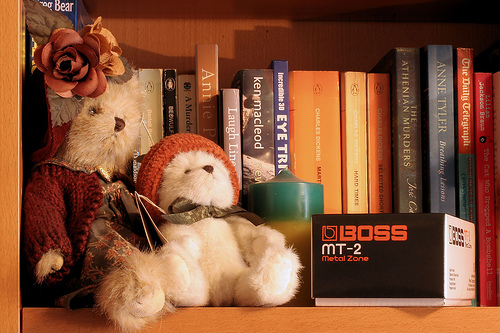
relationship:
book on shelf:
[426, 42, 461, 218] [6, 2, 497, 326]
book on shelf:
[471, 70, 499, 306] [6, 2, 497, 326]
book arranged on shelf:
[292, 69, 340, 216] [22, 308, 499, 332]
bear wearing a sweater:
[93, 130, 301, 328] [34, 134, 154, 310]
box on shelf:
[309, 212, 476, 306] [22, 305, 499, 331]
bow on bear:
[163, 197, 259, 222] [93, 130, 301, 328]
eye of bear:
[83, 101, 105, 123] [19, 77, 175, 328]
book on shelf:
[426, 42, 461, 218] [21, 303, 497, 329]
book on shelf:
[426, 42, 461, 218] [80, 40, 468, 329]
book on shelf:
[230, 62, 272, 190] [6, 2, 497, 326]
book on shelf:
[426, 42, 461, 218] [228, 295, 483, 319]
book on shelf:
[341, 65, 369, 213] [16, 302, 499, 331]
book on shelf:
[426, 42, 456, 217] [16, 302, 499, 331]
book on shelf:
[455, 42, 475, 222] [16, 302, 499, 331]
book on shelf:
[221, 85, 241, 187] [16, 302, 499, 331]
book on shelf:
[194, 42, 219, 147] [16, 302, 499, 331]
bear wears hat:
[93, 130, 301, 328] [135, 124, 249, 189]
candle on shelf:
[263, 175, 333, 295] [46, 34, 489, 323]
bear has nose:
[135, 130, 301, 308] [199, 162, 213, 171]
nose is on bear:
[111, 113, 130, 132] [19, 77, 180, 322]